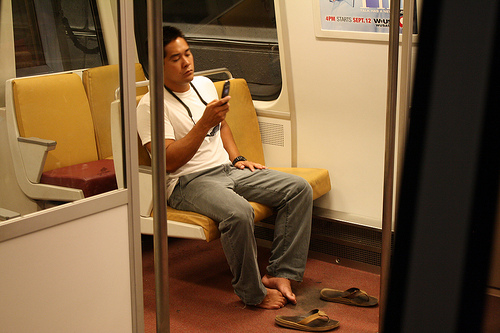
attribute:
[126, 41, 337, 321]
man — barefoot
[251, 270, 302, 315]
feet — bare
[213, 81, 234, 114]
phone — black, plastic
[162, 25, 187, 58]
hair — black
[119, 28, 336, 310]
man — holding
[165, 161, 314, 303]
jeans — gray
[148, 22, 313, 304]
man — barefoot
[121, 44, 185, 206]
pole — metal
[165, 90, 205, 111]
chain — black, fabric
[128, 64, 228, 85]
bar seat — metal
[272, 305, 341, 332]
sandal — brown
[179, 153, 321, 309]
pants — grey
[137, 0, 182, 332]
pole — gray, metal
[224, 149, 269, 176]
watch — black, plastic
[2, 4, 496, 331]
subway car — subway 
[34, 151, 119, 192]
cushion — red